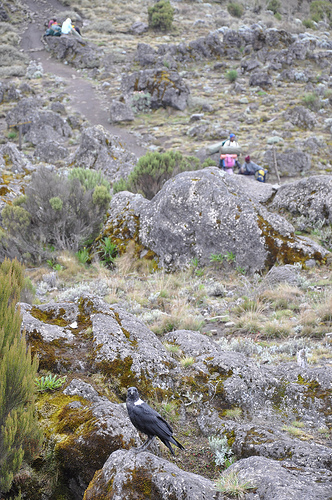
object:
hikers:
[217, 133, 239, 173]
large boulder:
[26, 161, 112, 256]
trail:
[59, 63, 140, 152]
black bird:
[123, 386, 186, 452]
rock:
[80, 446, 192, 499]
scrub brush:
[131, 145, 174, 197]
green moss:
[257, 213, 323, 268]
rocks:
[139, 167, 287, 272]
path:
[66, 63, 101, 122]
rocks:
[108, 91, 133, 127]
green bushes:
[72, 167, 109, 208]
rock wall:
[117, 63, 192, 109]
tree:
[146, 0, 175, 28]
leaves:
[151, 5, 160, 17]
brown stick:
[272, 146, 283, 186]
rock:
[260, 146, 299, 175]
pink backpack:
[220, 152, 238, 167]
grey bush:
[239, 295, 267, 324]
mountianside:
[43, 15, 105, 69]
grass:
[96, 232, 120, 264]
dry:
[134, 313, 155, 342]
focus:
[208, 121, 240, 146]